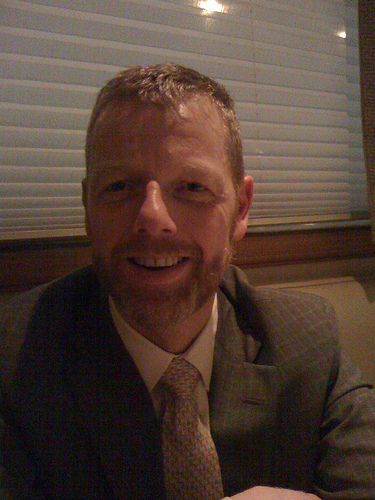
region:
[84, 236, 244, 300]
man with white teeth is smiling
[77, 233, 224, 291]
man with white teeth is smiling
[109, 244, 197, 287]
man with white teeth is smiling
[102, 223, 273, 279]
man with white teeth is smiling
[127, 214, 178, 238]
nostrils of smiling man in suit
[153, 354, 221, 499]
patterned tie of smiling man in suit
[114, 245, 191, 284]
upper teeth of smiling man in suit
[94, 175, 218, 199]
eyes of smiling bearded man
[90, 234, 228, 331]
beard and mouth of smiling man in suit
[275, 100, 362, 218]
part of white close blinds behind man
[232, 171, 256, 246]
one ear of smiling bearded man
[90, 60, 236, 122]
top of smiling bearded man's head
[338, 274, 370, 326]
seat that smiling bearded man is sitting against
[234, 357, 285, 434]
lapel button on suit of smiling bearded man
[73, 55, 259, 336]
The head of a man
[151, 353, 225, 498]
A necktie with a pattern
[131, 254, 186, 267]
Seven upper teeth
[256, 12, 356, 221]
White blinds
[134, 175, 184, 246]
The nose of a man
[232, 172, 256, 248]
The ear of a man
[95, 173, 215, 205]
The eyes of a man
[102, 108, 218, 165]
A man's forehead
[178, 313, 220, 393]
The collar of a white shirt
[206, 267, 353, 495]
A dark gray business suit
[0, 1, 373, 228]
White window shade behind man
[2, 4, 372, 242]
Glass window behind a man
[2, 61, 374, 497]
Man with red hair in suit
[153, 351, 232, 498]
Tie hanging from neck of man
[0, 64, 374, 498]
White man smiling while sitting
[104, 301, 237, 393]
Man's shirt collar with tie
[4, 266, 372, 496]
Man's fancy dress up suit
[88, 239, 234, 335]
Mans red beard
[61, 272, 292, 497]
Man's suit lapel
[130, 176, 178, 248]
Man's large nose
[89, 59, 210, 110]
Short light brown hair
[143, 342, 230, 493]
Colorful knotted tie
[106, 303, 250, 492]
White collared shirt with tie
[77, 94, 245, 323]
A man's face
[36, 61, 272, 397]
A man in a suit smiling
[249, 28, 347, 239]
Blinds in a window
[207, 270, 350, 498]
A brown suit jacket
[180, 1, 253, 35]
A light reflecting on the blinds in the window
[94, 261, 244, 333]
A man's beard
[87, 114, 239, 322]
A man showing teeth when he smiles